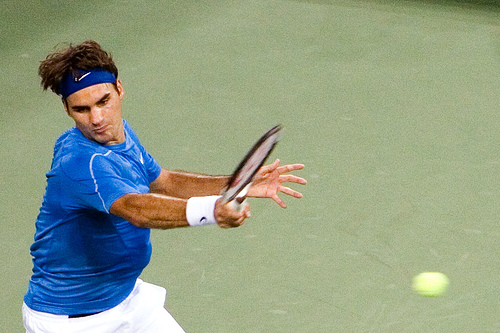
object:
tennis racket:
[219, 123, 283, 213]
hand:
[213, 198, 251, 229]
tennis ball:
[410, 270, 450, 297]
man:
[21, 40, 308, 333]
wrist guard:
[186, 194, 224, 227]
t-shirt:
[22, 118, 161, 314]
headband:
[62, 70, 117, 99]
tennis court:
[0, 1, 499, 333]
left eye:
[99, 98, 109, 105]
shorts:
[20, 278, 187, 333]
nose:
[88, 106, 104, 125]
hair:
[37, 38, 120, 94]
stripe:
[88, 149, 111, 214]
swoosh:
[74, 71, 92, 82]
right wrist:
[185, 195, 216, 226]